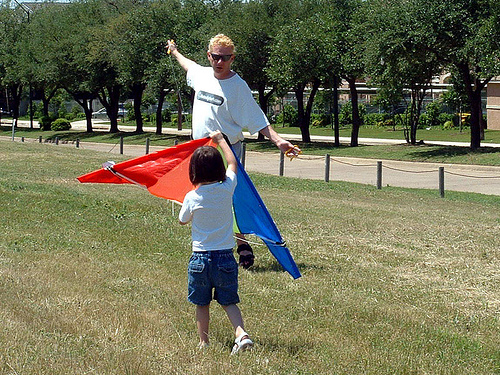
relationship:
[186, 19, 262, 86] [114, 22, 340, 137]
head of man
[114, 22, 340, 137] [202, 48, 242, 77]
man has face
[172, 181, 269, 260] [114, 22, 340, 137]
shirt on man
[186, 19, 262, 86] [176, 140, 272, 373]
head of girl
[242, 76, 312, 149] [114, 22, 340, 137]
arm of man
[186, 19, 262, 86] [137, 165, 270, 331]
head of child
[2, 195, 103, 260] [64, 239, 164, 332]
grass on ground